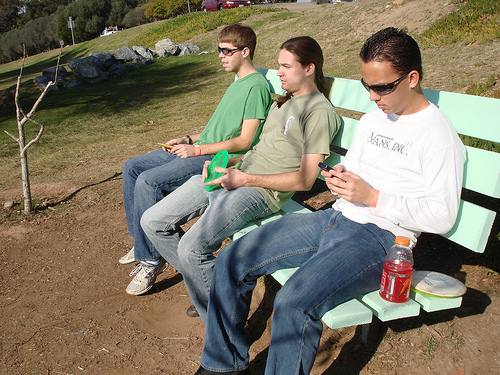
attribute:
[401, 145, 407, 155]
letter — black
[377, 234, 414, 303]
bottle — plastic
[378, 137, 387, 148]
letter — black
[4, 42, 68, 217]
tree — bare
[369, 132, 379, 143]
letter — black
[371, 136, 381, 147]
letter — black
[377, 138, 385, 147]
letter — black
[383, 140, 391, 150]
letter — black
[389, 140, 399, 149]
letter — black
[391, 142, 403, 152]
letter — black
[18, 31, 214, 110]
rocks — gray , large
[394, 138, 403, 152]
letter — black